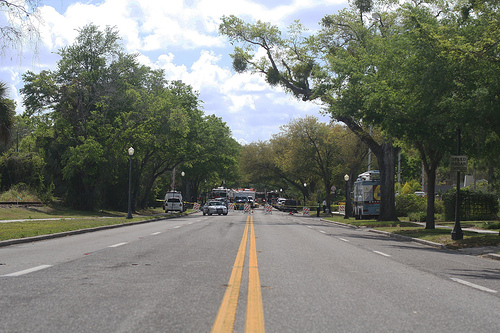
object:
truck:
[352, 170, 380, 220]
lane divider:
[240, 222, 263, 317]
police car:
[203, 201, 228, 215]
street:
[197, 221, 230, 247]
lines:
[319, 229, 391, 257]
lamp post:
[344, 174, 351, 219]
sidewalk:
[412, 218, 427, 229]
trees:
[186, 105, 234, 188]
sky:
[184, 31, 219, 67]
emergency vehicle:
[212, 187, 256, 209]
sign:
[451, 152, 468, 172]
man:
[322, 199, 327, 214]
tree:
[327, 175, 335, 206]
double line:
[221, 217, 263, 305]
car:
[277, 198, 298, 213]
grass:
[358, 220, 377, 226]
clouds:
[163, 19, 190, 43]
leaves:
[422, 59, 439, 74]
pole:
[126, 147, 135, 219]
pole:
[451, 171, 463, 239]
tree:
[417, 174, 440, 226]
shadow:
[337, 226, 427, 251]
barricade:
[264, 204, 273, 215]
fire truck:
[212, 187, 256, 207]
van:
[163, 191, 183, 213]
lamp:
[303, 183, 307, 207]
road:
[268, 221, 289, 241]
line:
[6, 220, 198, 278]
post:
[451, 171, 463, 239]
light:
[128, 147, 135, 156]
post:
[126, 155, 133, 219]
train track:
[5, 197, 43, 211]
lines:
[226, 226, 271, 285]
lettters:
[453, 157, 466, 161]